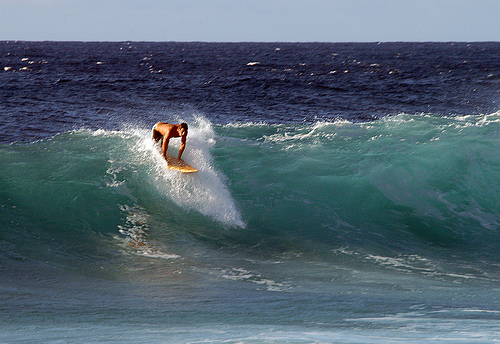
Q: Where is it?
A: This is at the ocean.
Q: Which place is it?
A: It is an ocean.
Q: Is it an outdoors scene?
A: Yes, it is outdoors.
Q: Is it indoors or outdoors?
A: It is outdoors.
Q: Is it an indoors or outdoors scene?
A: It is outdoors.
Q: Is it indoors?
A: No, it is outdoors.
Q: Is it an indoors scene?
A: No, it is outdoors.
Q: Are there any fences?
A: No, there are no fences.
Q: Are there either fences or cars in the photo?
A: No, there are no fences or cars.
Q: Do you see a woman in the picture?
A: No, there are no women.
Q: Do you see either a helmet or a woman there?
A: No, there are no women or helmets.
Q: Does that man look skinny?
A: Yes, the man is skinny.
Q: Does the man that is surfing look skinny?
A: Yes, the man is skinny.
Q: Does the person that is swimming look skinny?
A: Yes, the man is skinny.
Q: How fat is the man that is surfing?
A: The man is skinny.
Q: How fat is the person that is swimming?
A: The man is skinny.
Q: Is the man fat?
A: No, the man is skinny.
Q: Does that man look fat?
A: No, the man is skinny.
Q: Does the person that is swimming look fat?
A: No, the man is skinny.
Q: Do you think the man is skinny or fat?
A: The man is skinny.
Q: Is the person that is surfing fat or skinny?
A: The man is skinny.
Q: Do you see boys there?
A: No, there are no boys.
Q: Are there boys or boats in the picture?
A: No, there are no boys or boats.